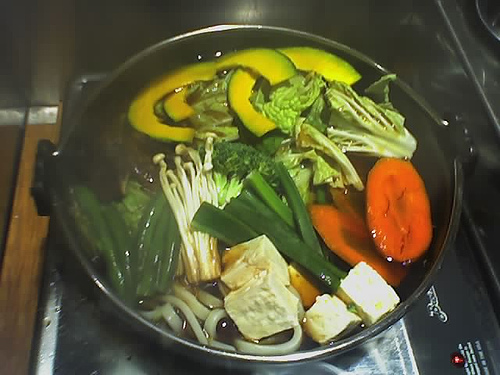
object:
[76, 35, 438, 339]
vegetables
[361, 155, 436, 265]
carrot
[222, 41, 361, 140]
avocado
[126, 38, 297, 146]
avocado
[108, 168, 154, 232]
cabbage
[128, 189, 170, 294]
green beans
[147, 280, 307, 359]
noodles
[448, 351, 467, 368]
light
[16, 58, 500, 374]
stove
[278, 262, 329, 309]
plantain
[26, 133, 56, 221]
handle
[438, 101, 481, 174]
handle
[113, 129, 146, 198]
green peppers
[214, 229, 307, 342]
tofu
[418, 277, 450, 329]
brand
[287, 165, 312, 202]
onion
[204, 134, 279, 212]
broccoli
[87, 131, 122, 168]
liquid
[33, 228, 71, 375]
white edge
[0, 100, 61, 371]
wood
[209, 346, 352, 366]
shiny edge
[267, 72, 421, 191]
lettuce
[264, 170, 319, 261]
scallions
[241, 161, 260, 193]
edge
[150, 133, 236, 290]
bean sprouts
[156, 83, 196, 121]
slice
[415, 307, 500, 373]
right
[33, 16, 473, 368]
pot